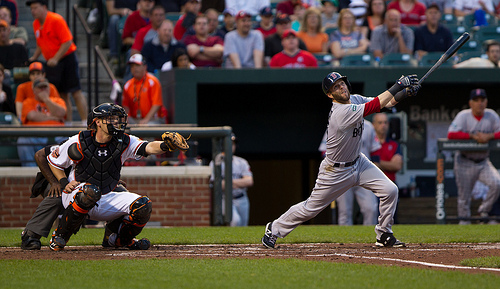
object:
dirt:
[0, 241, 499, 274]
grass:
[0, 224, 499, 248]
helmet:
[317, 70, 350, 98]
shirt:
[445, 108, 499, 160]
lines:
[106, 252, 338, 260]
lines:
[395, 246, 499, 251]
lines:
[335, 252, 498, 271]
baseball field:
[0, 224, 499, 288]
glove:
[158, 130, 190, 155]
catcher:
[42, 102, 190, 251]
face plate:
[98, 105, 132, 141]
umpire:
[17, 123, 134, 251]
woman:
[291, 6, 331, 55]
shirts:
[117, 69, 169, 118]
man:
[220, 10, 268, 71]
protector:
[66, 126, 130, 195]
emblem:
[326, 72, 342, 82]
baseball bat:
[407, 31, 472, 96]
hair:
[296, 6, 324, 34]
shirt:
[220, 28, 266, 70]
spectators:
[13, 60, 62, 121]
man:
[443, 88, 499, 227]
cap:
[469, 84, 489, 102]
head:
[317, 69, 351, 102]